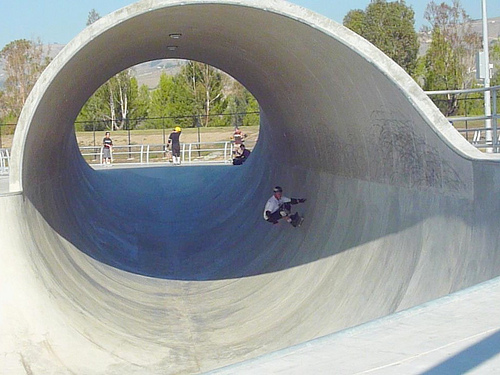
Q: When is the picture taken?
A: Daytime.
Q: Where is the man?
A: At a skatepark.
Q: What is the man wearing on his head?
A: A helmet.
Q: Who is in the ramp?
A: A man.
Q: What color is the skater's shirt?
A: White.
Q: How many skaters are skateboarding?
A: 1.